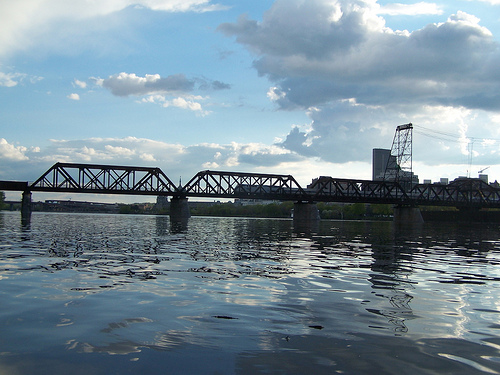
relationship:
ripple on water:
[245, 236, 308, 308] [145, 223, 391, 339]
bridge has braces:
[1, 121, 374, 214] [138, 168, 180, 196]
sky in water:
[171, 37, 230, 68] [145, 223, 391, 339]